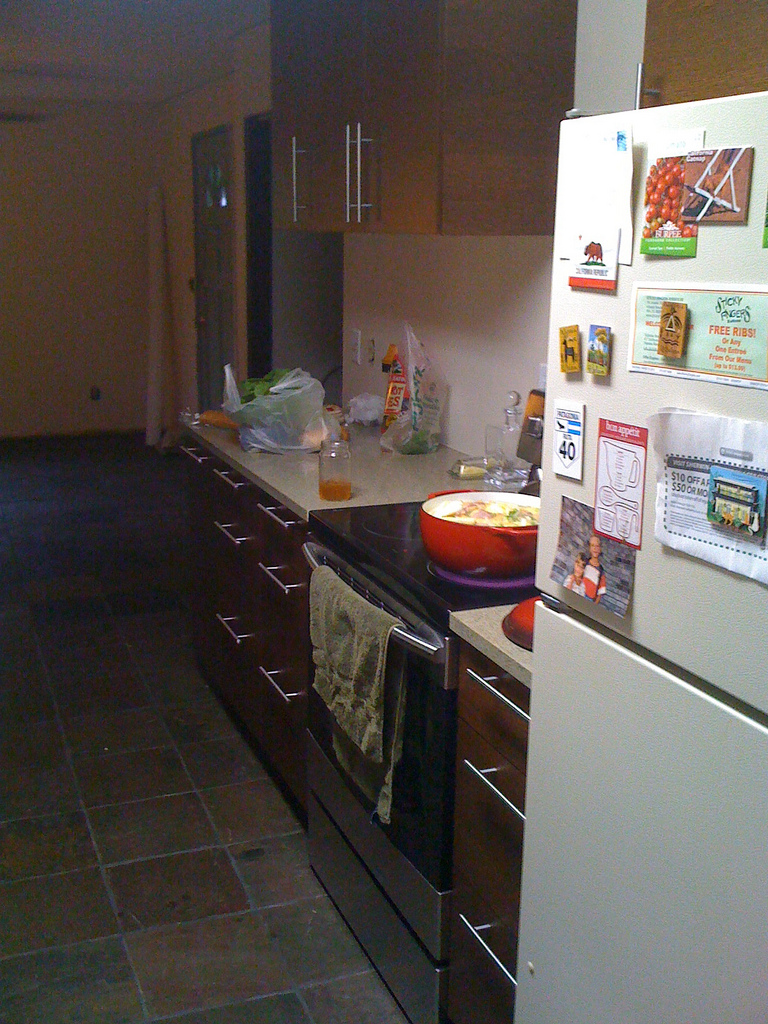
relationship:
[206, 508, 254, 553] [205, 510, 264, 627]
handle on drawer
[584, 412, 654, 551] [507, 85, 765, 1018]
magnet on fridge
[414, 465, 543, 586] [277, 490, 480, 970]
bowl ont he stove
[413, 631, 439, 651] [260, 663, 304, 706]
silver drawer handle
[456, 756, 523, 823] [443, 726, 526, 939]
handle on drawer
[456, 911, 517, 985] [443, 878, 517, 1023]
handle on drawer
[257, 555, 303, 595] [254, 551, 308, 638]
handle on drawer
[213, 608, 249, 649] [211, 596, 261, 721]
handle on drawer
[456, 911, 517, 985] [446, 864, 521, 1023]
handle on drawer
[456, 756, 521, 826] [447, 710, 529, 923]
handle on drawer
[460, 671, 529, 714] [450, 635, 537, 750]
handle on drawer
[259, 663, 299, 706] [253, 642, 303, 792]
handle on drawer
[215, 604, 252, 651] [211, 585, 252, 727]
handle on drawer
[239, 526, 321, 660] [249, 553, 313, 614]
drawer has handle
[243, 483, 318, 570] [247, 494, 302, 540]
drawer has handle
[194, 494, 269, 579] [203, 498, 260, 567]
drawer has handle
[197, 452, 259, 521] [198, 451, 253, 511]
drawer has handle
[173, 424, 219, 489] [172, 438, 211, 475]
drawer has handle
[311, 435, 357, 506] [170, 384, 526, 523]
jar on table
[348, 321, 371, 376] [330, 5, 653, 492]
outlet on wall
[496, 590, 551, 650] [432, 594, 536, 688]
top on table